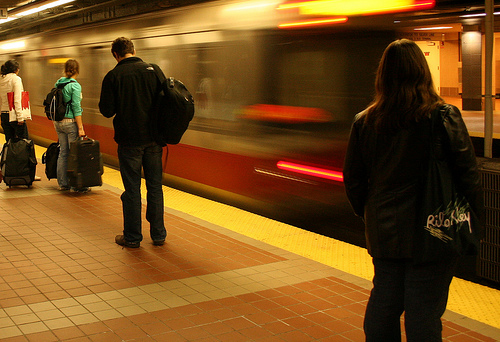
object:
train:
[0, 11, 495, 234]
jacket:
[0, 73, 25, 122]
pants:
[116, 141, 168, 243]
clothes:
[97, 54, 174, 148]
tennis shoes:
[115, 235, 140, 249]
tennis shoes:
[152, 235, 165, 245]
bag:
[420, 102, 483, 258]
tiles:
[62, 217, 149, 305]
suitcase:
[71, 134, 106, 192]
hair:
[360, 37, 446, 128]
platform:
[25, 247, 406, 337]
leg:
[55, 129, 70, 187]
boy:
[97, 33, 168, 249]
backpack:
[153, 77, 196, 145]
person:
[0, 58, 43, 183]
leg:
[398, 226, 451, 340]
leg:
[363, 214, 408, 340]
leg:
[140, 146, 175, 247]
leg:
[65, 129, 79, 149]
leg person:
[348, 32, 471, 339]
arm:
[14, 82, 24, 123]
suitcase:
[42, 75, 77, 121]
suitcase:
[41, 139, 61, 181]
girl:
[52, 58, 92, 193]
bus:
[0, 0, 496, 280]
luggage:
[64, 137, 103, 193]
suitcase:
[0, 138, 39, 191]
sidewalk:
[6, 175, 361, 336]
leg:
[10, 120, 29, 145]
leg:
[119, 139, 145, 243]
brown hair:
[110, 36, 135, 59]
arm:
[72, 82, 86, 137]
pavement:
[88, 283, 281, 320]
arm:
[97, 72, 116, 118]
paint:
[212, 270, 242, 284]